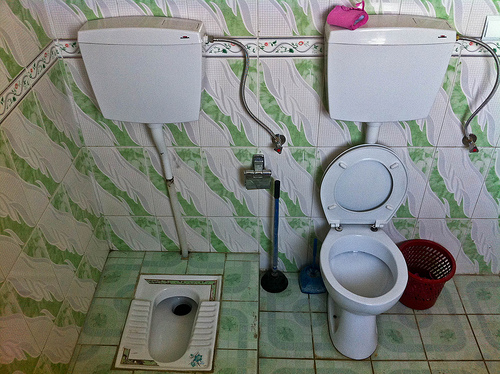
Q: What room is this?
A: A bathroom.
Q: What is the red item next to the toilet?
A: A wastebasket.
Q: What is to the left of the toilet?
A: Some type of urinal.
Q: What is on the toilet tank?
A: A pink item.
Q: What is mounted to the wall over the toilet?
A: The tank.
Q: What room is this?
A: Bathroom.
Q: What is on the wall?
A: Green and white tile.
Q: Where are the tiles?
A: On the floor.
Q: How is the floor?
A: Tiled.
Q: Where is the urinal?
A: On the ground.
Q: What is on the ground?
A: The urinal.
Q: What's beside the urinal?
A: The toilet.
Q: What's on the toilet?
A: Something pink.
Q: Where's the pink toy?
A: On the toilet.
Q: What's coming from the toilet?
A: Pipe.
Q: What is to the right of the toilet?
A: A waste basket.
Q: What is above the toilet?
A: A white toilet tank.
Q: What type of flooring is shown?
A: Tile.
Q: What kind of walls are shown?
A: White and green tiled wall.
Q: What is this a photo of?
A: A bathroom.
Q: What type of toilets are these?
A: Traditional and European.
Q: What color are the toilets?
A: White.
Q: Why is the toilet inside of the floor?
A: Because certain cultures of people squat and use the bathroom instead of sitting.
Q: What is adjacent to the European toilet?
A: A red wastebasket.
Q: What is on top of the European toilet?
A: A hot pink change purse.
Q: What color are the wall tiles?
A: Green and white.